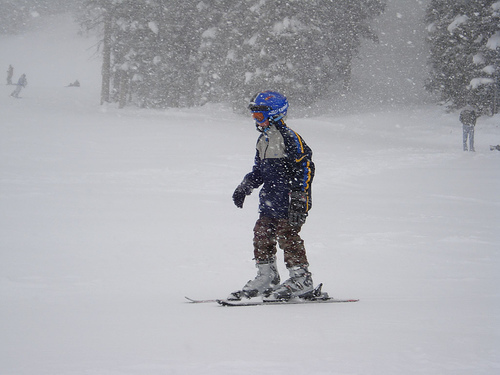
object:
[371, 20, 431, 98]
snow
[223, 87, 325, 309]
skier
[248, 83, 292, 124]
helmet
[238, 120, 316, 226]
coat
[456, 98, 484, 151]
person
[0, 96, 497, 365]
field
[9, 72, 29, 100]
skiers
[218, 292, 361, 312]
skis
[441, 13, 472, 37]
snow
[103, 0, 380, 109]
trees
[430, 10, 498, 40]
branches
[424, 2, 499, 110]
tree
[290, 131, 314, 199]
stripe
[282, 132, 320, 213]
sleeve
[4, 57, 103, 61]
background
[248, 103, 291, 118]
goggles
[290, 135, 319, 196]
arms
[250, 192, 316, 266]
pants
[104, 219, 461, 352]
snow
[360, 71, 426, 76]
background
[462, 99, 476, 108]
head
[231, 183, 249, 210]
hand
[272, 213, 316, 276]
leg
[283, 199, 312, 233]
gloves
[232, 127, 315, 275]
snow suit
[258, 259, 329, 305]
ski boots